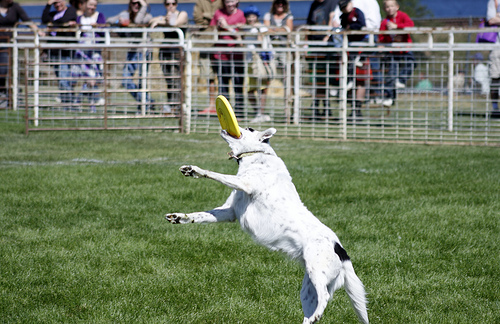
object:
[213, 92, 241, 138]
frisbee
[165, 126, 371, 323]
dog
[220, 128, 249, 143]
mouth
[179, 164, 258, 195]
leg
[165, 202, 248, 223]
front right leg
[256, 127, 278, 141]
left ear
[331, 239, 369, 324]
tail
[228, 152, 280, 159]
collar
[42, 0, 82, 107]
spectators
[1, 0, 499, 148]
distance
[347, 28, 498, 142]
fence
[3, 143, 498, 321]
grass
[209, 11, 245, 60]
shirt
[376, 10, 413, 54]
shirt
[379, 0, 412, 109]
child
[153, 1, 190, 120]
woman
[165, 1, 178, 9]
sunglasses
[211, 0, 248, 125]
woman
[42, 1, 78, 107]
person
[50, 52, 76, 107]
jeans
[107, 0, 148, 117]
women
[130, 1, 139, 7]
sunglasses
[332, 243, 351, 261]
spot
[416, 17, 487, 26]
roof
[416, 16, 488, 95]
building